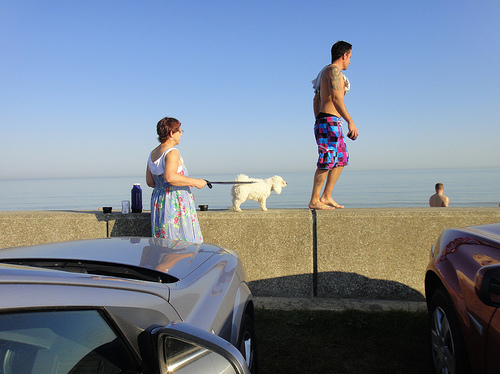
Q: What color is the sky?
A: Blue.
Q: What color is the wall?
A: Grey.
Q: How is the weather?
A: Clear.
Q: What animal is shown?
A: A dog.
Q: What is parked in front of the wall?
A: Two cars.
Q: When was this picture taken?
A: Daytime.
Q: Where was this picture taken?
A: The seaside.